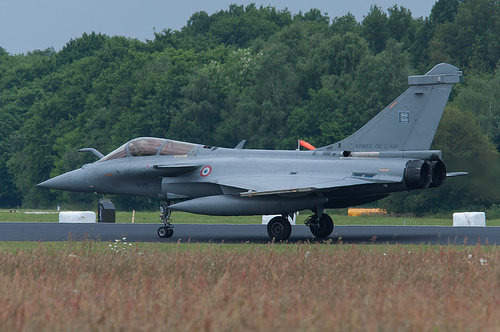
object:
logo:
[200, 164, 211, 176]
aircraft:
[33, 63, 468, 241]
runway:
[0, 222, 499, 243]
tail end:
[378, 59, 461, 193]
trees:
[334, 42, 421, 140]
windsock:
[298, 139, 316, 150]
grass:
[119, 215, 154, 223]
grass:
[464, 243, 497, 264]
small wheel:
[157, 226, 174, 238]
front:
[34, 127, 137, 206]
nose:
[36, 170, 81, 194]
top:
[114, 134, 204, 149]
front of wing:
[172, 176, 251, 194]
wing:
[163, 173, 399, 199]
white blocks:
[59, 211, 97, 223]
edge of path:
[0, 221, 498, 229]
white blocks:
[261, 214, 295, 225]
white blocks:
[452, 212, 486, 228]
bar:
[406, 72, 463, 86]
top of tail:
[402, 60, 466, 88]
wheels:
[308, 212, 334, 237]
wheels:
[266, 216, 292, 242]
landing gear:
[304, 204, 324, 226]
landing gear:
[287, 209, 294, 219]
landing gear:
[165, 211, 175, 229]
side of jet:
[33, 162, 416, 198]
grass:
[0, 250, 29, 270]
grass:
[1, 240, 15, 249]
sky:
[0, 1, 183, 37]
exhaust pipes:
[405, 157, 432, 191]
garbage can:
[95, 197, 115, 225]